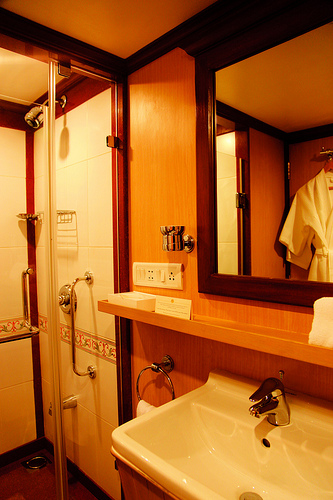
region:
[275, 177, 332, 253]
reflection of robe in mirror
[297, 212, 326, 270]
robe in mirror is white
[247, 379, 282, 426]
single chrome sink faucet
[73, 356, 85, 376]
stainless handle in shower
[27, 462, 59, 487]
stainless drain in floor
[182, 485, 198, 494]
sunk is white porcelain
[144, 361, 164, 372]
stainless towel holder on wall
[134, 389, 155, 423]
white towel on holder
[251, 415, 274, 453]
shadow of faucet on sink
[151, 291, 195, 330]
white sign on shelf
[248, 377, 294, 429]
silver faucet on a sink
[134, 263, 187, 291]
electrical outlet on a wall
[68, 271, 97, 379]
hand rail in a shower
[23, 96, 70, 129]
silver shower head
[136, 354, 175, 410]
silver towel holder in a bathroom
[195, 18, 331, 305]
mirror in a bathroom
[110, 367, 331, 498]
sink in a bathroom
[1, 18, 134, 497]
shower in a bathroom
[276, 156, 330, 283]
bath robe hanging in a bathroom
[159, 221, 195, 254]
silver light fixture on a wall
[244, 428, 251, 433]
part of a sink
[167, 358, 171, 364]
part of a wall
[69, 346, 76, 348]
part of a rail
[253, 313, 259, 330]
part of a window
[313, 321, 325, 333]
part of a towel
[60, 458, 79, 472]
part of a floor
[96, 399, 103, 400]
side of a wall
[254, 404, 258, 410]
side of a tap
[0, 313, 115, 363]
decorative tiles in show stall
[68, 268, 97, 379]
handle bar in show stall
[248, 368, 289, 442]
faucet casts shadow on bathroom sink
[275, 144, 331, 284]
bathrobe hangs on bathroom door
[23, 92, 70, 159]
shower head casts show on shower stall wall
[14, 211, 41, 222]
soap tray hangs in shower stall corner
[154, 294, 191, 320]
hotel room guest information placard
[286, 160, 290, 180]
bathroom door hinge reflected in mirror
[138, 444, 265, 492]
bathroom sink reflects camera's flah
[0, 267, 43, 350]
glass door handle combination towel rack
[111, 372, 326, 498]
the sink is against the wall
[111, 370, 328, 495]
the sink is white in color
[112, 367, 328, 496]
the sink is made of ceramic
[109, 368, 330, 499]
the sink is shiny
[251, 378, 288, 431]
the faucet is made of metal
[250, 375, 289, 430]
the faucet is shiny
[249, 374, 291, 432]
the faucet is made of steel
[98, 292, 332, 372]
a shelf is on the wall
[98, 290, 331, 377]
the shelf is made of wood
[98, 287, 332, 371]
the shelf is light brown in color